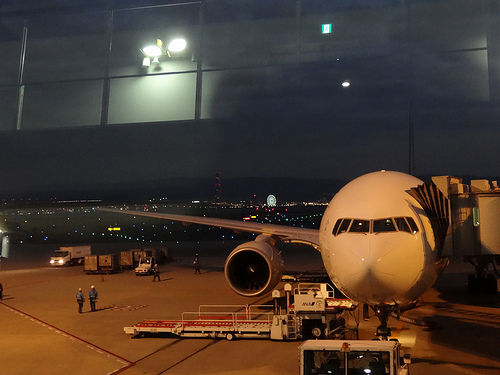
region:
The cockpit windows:
[334, 218, 416, 233]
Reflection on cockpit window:
[357, 222, 362, 225]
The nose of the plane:
[353, 249, 389, 284]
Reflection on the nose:
[360, 256, 382, 262]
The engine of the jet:
[234, 249, 266, 289]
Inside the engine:
[239, 257, 259, 284]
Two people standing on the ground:
[75, 284, 97, 313]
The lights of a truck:
[50, 259, 62, 263]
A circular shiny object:
[267, 195, 274, 205]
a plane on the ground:
[130, 73, 437, 347]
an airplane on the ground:
[293, 169, 465, 368]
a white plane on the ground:
[290, 131, 436, 353]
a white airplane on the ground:
[250, 127, 458, 366]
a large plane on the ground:
[289, 90, 461, 374]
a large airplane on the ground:
[299, 123, 420, 346]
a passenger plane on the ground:
[293, 122, 436, 362]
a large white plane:
[275, 127, 486, 304]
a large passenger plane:
[336, 116, 461, 356]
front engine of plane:
[222, 237, 279, 299]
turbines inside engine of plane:
[239, 256, 258, 280]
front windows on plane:
[331, 208, 420, 245]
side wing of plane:
[86, 202, 253, 254]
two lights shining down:
[140, 36, 194, 72]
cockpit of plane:
[336, 193, 413, 275]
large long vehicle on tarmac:
[132, 289, 317, 340]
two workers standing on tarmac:
[70, 283, 100, 314]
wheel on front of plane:
[366, 315, 396, 349]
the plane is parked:
[226, 145, 468, 340]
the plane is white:
[287, 120, 459, 315]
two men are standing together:
[50, 267, 120, 320]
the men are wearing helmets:
[66, 280, 101, 294]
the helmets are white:
[61, 279, 103, 296]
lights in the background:
[178, 161, 321, 231]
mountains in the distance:
[129, 160, 313, 192]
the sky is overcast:
[132, 72, 465, 196]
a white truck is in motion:
[36, 229, 91, 274]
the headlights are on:
[40, 253, 70, 276]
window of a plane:
[334, 212, 419, 241]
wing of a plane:
[88, 177, 218, 242]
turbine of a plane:
[216, 245, 285, 295]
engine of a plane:
[215, 245, 273, 296]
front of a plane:
[296, 164, 437, 304]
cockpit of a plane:
[323, 211, 422, 258]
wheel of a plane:
[370, 320, 401, 338]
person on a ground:
[65, 267, 118, 318]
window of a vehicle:
[303, 345, 393, 374]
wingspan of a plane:
[80, 198, 230, 255]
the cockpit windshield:
[330, 214, 418, 236]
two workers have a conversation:
[73, 284, 99, 312]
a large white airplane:
[92, 170, 449, 342]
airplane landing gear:
[371, 302, 398, 342]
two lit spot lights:
[139, 35, 188, 56]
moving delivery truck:
[47, 243, 93, 268]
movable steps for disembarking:
[123, 282, 355, 339]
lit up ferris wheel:
[265, 193, 277, 206]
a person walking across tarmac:
[150, 262, 161, 282]